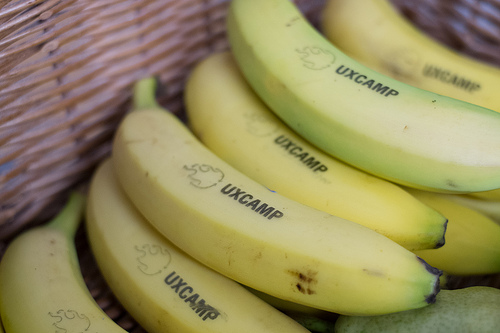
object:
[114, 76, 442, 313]
banana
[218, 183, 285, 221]
lettering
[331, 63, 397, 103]
uxcamp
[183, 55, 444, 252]
bananas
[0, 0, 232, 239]
basket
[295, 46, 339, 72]
design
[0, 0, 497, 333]
scene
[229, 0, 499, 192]
banana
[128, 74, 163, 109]
stem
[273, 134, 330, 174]
stamps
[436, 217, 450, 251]
bottom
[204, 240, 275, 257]
skin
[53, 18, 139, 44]
grooves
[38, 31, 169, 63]
lines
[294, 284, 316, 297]
spots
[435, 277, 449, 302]
tip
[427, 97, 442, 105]
spot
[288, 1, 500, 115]
edge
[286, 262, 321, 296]
bruising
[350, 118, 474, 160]
peel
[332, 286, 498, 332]
stone